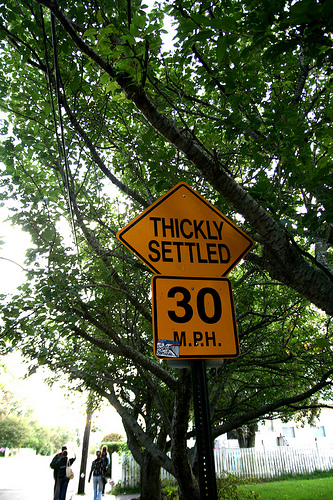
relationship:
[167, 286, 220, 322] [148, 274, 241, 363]
number on sign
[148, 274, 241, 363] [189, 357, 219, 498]
sign on pole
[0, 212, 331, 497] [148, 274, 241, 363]
tree behind sign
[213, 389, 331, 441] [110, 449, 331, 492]
house behind fence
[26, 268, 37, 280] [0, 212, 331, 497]
leaf on tree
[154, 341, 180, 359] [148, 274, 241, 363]
sticker on sign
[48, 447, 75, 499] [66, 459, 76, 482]
person carrying bag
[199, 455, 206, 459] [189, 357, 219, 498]
hole in pole